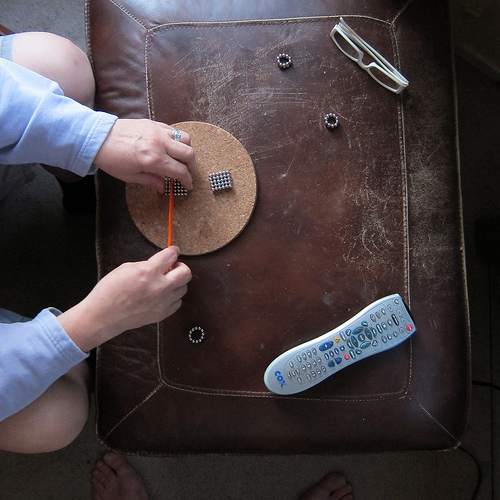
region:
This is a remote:
[317, 306, 403, 387]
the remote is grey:
[290, 302, 405, 381]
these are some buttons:
[282, 256, 337, 346]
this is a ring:
[155, 333, 222, 344]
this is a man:
[29, 260, 152, 356]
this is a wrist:
[86, 304, 128, 362]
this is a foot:
[95, 469, 107, 479]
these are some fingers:
[151, 228, 243, 333]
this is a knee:
[35, 340, 85, 478]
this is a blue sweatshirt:
[1, 371, 86, 419]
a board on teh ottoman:
[112, 113, 272, 248]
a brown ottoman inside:
[104, 71, 444, 396]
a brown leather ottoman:
[136, 90, 393, 413]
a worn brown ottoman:
[62, 64, 499, 482]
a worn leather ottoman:
[18, 56, 453, 427]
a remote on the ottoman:
[177, 282, 467, 424]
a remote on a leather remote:
[264, 257, 417, 406]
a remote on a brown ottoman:
[260, 274, 412, 386]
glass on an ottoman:
[294, 4, 413, 94]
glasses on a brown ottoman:
[308, 13, 460, 153]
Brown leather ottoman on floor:
[83, 1, 472, 455]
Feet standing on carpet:
[89, 446, 364, 498]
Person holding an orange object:
[0, 62, 202, 453]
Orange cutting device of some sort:
[164, 175, 175, 250]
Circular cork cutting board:
[123, 121, 258, 256]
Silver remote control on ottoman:
[262, 293, 417, 395]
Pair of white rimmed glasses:
[329, 15, 411, 95]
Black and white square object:
[208, 168, 233, 193]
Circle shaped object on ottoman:
[322, 112, 339, 127]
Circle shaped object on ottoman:
[187, 323, 207, 343]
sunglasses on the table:
[295, 26, 405, 93]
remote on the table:
[269, 290, 413, 399]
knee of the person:
[5, 397, 74, 441]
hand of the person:
[91, 246, 170, 328]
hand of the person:
[102, 115, 172, 198]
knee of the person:
[66, 73, 92, 98]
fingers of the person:
[146, 243, 183, 310]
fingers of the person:
[160, 136, 199, 187]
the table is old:
[332, 184, 385, 219]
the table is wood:
[216, 60, 290, 95]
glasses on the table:
[312, 8, 409, 108]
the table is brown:
[206, 236, 304, 283]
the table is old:
[349, 187, 449, 267]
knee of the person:
[20, 387, 86, 452]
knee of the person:
[19, 35, 94, 105]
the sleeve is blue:
[7, 343, 62, 383]